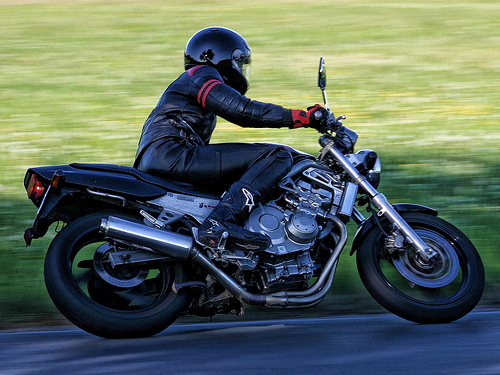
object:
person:
[132, 26, 327, 251]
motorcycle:
[23, 56, 485, 339]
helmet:
[184, 26, 252, 95]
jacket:
[131, 65, 293, 167]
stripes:
[197, 78, 223, 107]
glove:
[288, 103, 328, 134]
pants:
[134, 137, 294, 194]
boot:
[197, 182, 272, 251]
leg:
[177, 142, 293, 218]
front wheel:
[355, 211, 484, 323]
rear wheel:
[44, 211, 195, 338]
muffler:
[98, 215, 194, 260]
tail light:
[26, 173, 46, 198]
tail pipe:
[96, 217, 108, 232]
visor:
[231, 48, 252, 90]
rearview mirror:
[317, 57, 325, 90]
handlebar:
[312, 108, 324, 121]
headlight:
[355, 149, 381, 190]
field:
[0, 0, 498, 330]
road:
[0, 308, 500, 373]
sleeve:
[187, 65, 291, 128]